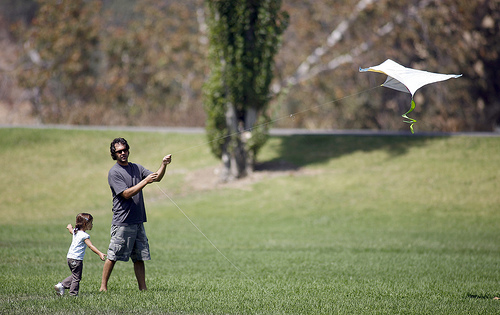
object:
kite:
[358, 58, 461, 135]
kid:
[53, 211, 108, 298]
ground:
[0, 127, 499, 314]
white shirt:
[65, 228, 92, 260]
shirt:
[106, 160, 155, 226]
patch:
[0, 125, 499, 314]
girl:
[52, 212, 107, 297]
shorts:
[103, 222, 153, 261]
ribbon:
[400, 96, 418, 135]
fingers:
[162, 158, 168, 164]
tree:
[203, 0, 293, 182]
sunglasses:
[110, 147, 130, 154]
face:
[111, 141, 131, 164]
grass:
[2, 130, 499, 315]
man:
[98, 138, 175, 294]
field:
[0, 127, 500, 314]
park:
[2, 123, 500, 315]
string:
[169, 82, 392, 158]